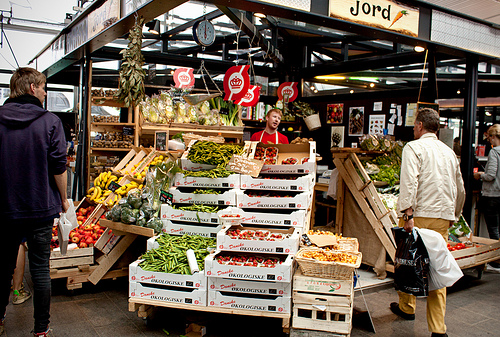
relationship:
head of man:
[372, 96, 469, 296] [358, 98, 474, 304]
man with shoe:
[358, 98, 474, 304] [370, 288, 463, 335]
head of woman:
[478, 115, 496, 146] [469, 102, 496, 213]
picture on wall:
[363, 12, 410, 41] [306, 99, 395, 159]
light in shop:
[153, 15, 204, 30] [32, 32, 459, 305]